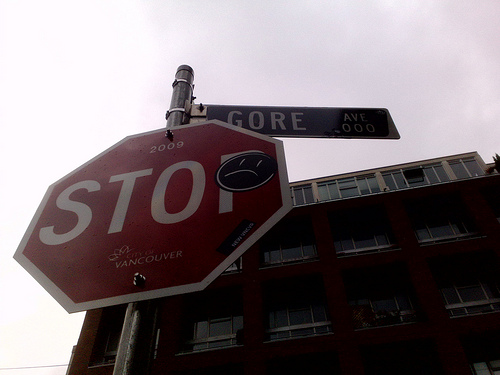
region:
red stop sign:
[14, 116, 293, 316]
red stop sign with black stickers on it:
[12, 118, 299, 315]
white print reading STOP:
[41, 153, 268, 249]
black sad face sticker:
[216, 147, 278, 192]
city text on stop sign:
[111, 241, 184, 271]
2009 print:
[143, 139, 192, 155]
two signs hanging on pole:
[11, 64, 411, 370]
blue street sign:
[186, 104, 404, 141]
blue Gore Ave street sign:
[190, 104, 400, 134]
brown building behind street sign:
[11, 62, 499, 372]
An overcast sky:
[291, 28, 366, 68]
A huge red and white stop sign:
[5, 114, 283, 297]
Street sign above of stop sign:
[227, 105, 409, 136]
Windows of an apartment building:
[192, 317, 241, 346]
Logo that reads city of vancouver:
[114, 239, 199, 271]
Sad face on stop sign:
[214, 145, 282, 209]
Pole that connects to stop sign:
[115, 316, 161, 373]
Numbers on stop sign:
[148, 140, 196, 153]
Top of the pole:
[172, 56, 197, 79]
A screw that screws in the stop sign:
[128, 272, 148, 288]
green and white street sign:
[196, 101, 400, 148]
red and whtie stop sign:
[10, 123, 295, 315]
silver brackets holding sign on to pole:
[156, 68, 201, 118]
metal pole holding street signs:
[103, 47, 191, 373]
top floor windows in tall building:
[272, 144, 497, 204]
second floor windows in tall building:
[277, 209, 497, 286]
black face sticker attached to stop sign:
[212, 134, 292, 209]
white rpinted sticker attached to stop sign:
[93, 231, 200, 308]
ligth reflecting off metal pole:
[101, 300, 162, 372]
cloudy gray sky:
[271, 26, 466, 106]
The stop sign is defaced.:
[11, 119, 284, 316]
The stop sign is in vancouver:
[12, 99, 291, 331]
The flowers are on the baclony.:
[365, 306, 412, 330]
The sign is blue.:
[197, 102, 402, 138]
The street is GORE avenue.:
[204, 103, 397, 138]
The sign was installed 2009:
[147, 139, 187, 153]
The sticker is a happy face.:
[211, 142, 281, 195]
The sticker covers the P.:
[216, 146, 273, 216]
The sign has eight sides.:
[12, 121, 294, 306]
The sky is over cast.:
[19, 61, 151, 121]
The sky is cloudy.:
[1, 0, 488, 175]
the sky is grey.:
[4, 2, 495, 175]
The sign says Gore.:
[205, 83, 405, 156]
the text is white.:
[205, 98, 406, 147]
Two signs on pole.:
[5, 91, 406, 318]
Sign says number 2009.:
[144, 137, 186, 155]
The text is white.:
[23, 135, 265, 255]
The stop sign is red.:
[12, 114, 297, 315]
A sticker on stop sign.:
[212, 145, 277, 195]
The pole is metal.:
[104, 62, 202, 372]